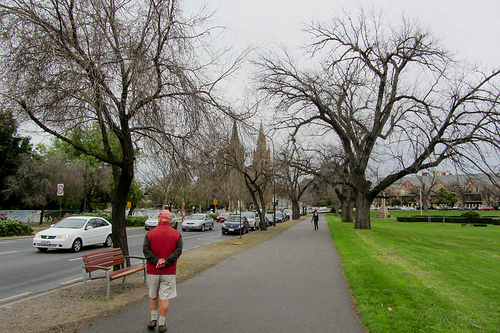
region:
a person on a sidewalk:
[302, 199, 337, 251]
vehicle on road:
[39, 208, 114, 260]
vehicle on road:
[140, 213, 169, 228]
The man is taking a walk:
[139, 212, 191, 326]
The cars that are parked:
[223, 205, 294, 230]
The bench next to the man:
[68, 241, 148, 291]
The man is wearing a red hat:
[156, 204, 178, 214]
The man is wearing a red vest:
[144, 223, 181, 283]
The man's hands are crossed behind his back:
[134, 232, 191, 274]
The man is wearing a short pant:
[143, 268, 190, 303]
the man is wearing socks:
[139, 301, 178, 322]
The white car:
[32, 197, 121, 254]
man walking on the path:
[140, 208, 184, 332]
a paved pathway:
[83, 210, 364, 331]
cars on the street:
[32, 200, 292, 252]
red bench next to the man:
[80, 247, 146, 298]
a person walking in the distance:
[310, 208, 320, 228]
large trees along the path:
[0, 0, 499, 272]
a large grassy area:
[326, 205, 499, 332]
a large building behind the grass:
[372, 171, 499, 211]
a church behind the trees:
[229, 115, 271, 182]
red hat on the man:
[156, 209, 172, 219]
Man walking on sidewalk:
[140, 207, 182, 330]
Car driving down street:
[27, 212, 111, 252]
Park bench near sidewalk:
[77, 245, 144, 295]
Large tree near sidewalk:
[245, 2, 497, 227]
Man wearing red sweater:
[142, 223, 183, 276]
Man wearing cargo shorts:
[144, 273, 176, 300]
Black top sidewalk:
[59, 212, 371, 329]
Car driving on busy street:
[180, 212, 212, 231]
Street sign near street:
[56, 184, 64, 195]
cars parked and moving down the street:
[2, 204, 295, 303]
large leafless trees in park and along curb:
[4, 5, 494, 272]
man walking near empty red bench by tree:
[76, 72, 185, 329]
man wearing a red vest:
[146, 225, 179, 274]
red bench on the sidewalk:
[76, 239, 155, 299]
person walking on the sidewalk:
[305, 205, 331, 238]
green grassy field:
[324, 207, 499, 331]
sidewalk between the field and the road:
[80, 213, 367, 332]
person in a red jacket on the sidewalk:
[142, 209, 182, 329]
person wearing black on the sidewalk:
[311, 208, 318, 228]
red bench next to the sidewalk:
[82, 248, 147, 298]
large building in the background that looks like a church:
[200, 117, 274, 212]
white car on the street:
[32, 216, 112, 255]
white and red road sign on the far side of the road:
[56, 180, 65, 197]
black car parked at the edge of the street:
[221, 213, 249, 233]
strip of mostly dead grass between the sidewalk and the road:
[0, 210, 311, 329]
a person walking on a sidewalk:
[144, 204, 189, 330]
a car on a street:
[36, 210, 118, 260]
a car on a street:
[119, 202, 148, 227]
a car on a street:
[147, 207, 179, 232]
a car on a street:
[180, 207, 212, 232]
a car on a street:
[220, 216, 257, 236]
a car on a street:
[232, 206, 257, 227]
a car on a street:
[212, 208, 232, 222]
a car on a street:
[265, 208, 275, 223]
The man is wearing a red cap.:
[148, 193, 178, 218]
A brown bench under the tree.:
[61, 245, 154, 296]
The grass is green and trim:
[364, 223, 489, 328]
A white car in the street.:
[50, 212, 111, 246]